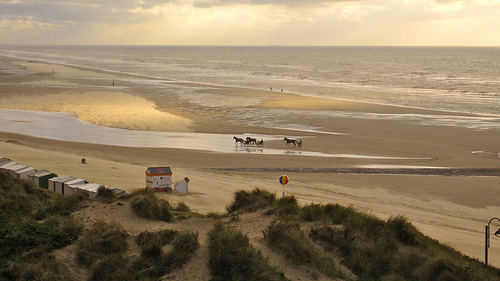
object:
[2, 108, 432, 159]
water pool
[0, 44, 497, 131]
ocean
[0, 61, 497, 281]
beach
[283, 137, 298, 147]
horse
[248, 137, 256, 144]
horse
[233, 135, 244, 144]
horse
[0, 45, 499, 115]
water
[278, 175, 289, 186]
ball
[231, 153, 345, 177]
dirt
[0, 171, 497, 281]
grass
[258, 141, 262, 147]
man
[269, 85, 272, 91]
person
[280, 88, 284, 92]
person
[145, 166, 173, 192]
shack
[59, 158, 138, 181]
sand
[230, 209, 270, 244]
dune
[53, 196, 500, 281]
cliff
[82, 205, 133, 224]
dune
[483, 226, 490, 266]
pole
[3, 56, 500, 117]
waterline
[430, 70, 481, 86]
wave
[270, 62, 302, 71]
wave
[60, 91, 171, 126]
sun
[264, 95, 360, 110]
ray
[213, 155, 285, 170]
sand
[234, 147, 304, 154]
reflection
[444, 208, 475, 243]
sand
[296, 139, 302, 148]
buggy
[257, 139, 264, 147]
buggy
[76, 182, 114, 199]
building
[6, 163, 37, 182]
building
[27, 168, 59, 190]
building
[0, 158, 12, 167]
building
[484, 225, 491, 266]
lamp post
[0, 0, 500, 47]
sky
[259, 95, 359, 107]
sunshine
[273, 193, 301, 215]
shrub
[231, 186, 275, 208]
shrub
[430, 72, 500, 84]
foam